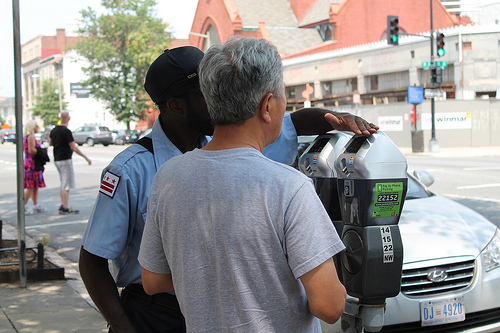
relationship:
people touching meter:
[78, 46, 380, 332] [298, 126, 408, 332]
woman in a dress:
[22, 121, 51, 216] [21, 135, 46, 190]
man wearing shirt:
[136, 36, 348, 332] [137, 146, 349, 331]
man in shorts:
[48, 109, 94, 212] [53, 158, 77, 189]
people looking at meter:
[80, 37, 380, 330] [298, 126, 408, 332]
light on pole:
[391, 34, 397, 43] [388, 1, 439, 146]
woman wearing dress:
[22, 121, 51, 216] [21, 135, 46, 190]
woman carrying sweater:
[22, 121, 51, 216] [32, 144, 53, 173]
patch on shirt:
[99, 169, 122, 198] [80, 111, 300, 296]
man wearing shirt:
[48, 109, 94, 212] [49, 124, 75, 161]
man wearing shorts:
[48, 109, 94, 212] [53, 158, 77, 189]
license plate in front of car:
[420, 293, 469, 327] [299, 140, 500, 332]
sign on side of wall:
[471, 57, 497, 91] [282, 26, 500, 146]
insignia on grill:
[427, 267, 450, 283] [400, 255, 477, 298]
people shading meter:
[78, 46, 380, 332] [298, 126, 408, 332]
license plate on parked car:
[420, 293, 469, 327] [299, 140, 500, 332]